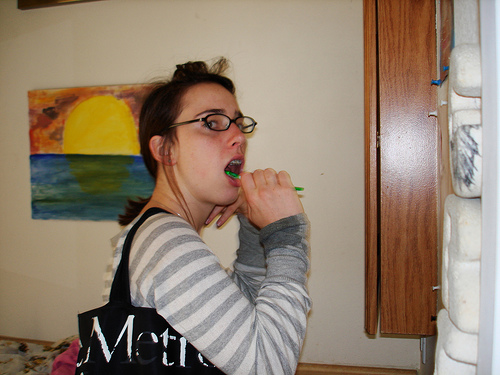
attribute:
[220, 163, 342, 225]
toothbrush — green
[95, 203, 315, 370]
sweater — grey, white, striped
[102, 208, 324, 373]
gray/whiteshirt — grey, white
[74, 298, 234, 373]
tote bag — black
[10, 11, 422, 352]
wall — white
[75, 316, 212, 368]
letters — white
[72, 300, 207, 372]
bag — black, white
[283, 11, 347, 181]
wall — white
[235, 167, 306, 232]
hand — holding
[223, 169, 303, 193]
toothbrush — green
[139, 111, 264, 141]
glasses — black